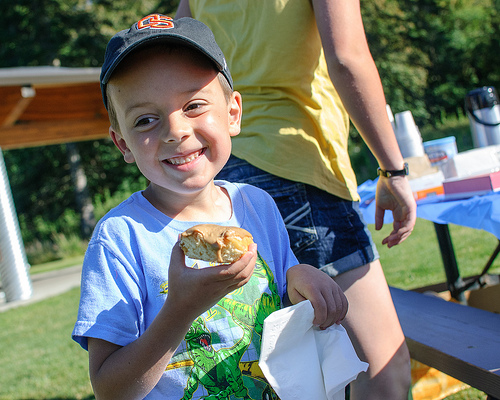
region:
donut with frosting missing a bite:
[173, 219, 255, 276]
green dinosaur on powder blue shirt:
[181, 314, 266, 399]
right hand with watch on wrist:
[368, 157, 419, 251]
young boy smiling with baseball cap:
[93, 6, 247, 203]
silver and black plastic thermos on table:
[461, 81, 498, 147]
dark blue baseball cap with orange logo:
[86, 6, 234, 103]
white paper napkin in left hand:
[255, 288, 377, 398]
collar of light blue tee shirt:
[111, 185, 251, 230]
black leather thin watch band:
[368, 160, 420, 184]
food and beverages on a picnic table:
[345, 87, 497, 394]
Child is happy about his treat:
[71, 13, 368, 398]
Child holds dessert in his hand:
[72, 12, 370, 398]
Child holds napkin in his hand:
[69, 12, 369, 397]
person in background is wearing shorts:
[175, 1, 421, 398]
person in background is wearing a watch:
[171, 2, 421, 399]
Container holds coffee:
[457, 84, 499, 149]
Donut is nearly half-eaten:
[175, 220, 253, 267]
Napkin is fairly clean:
[258, 301, 373, 398]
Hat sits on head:
[93, 13, 244, 194]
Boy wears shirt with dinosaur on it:
[72, 10, 349, 398]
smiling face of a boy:
[102, 14, 245, 192]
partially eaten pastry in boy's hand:
[180, 224, 255, 260]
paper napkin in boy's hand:
[262, 301, 368, 398]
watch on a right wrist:
[375, 159, 412, 180]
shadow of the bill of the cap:
[107, 50, 217, 145]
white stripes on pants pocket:
[286, 202, 314, 238]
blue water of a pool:
[416, 179, 498, 239]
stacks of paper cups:
[386, 103, 426, 159]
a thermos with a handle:
[462, 85, 498, 146]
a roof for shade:
[0, 67, 115, 147]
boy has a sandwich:
[48, 10, 345, 397]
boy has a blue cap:
[52, 0, 280, 261]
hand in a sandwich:
[159, 210, 267, 325]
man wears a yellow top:
[162, 0, 452, 390]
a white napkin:
[243, 295, 378, 397]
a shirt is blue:
[56, 180, 353, 395]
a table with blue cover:
[363, 94, 499, 288]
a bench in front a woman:
[241, 2, 498, 397]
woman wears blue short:
[202, 5, 437, 398]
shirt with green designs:
[81, 183, 316, 398]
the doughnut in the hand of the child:
[148, 207, 259, 284]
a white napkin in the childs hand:
[259, 286, 368, 398]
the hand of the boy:
[285, 263, 352, 333]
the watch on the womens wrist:
[368, 160, 415, 185]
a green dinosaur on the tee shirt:
[186, 315, 264, 398]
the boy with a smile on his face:
[82, 11, 255, 198]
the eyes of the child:
[122, 93, 219, 135]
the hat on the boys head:
[96, 9, 233, 94]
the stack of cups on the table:
[393, 104, 422, 162]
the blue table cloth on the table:
[420, 198, 497, 241]